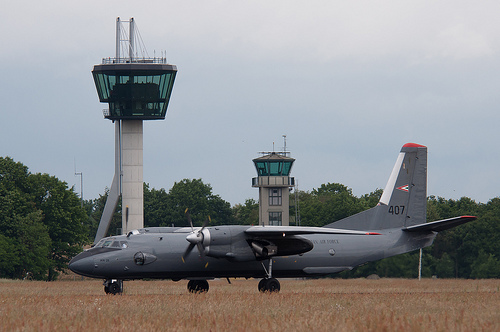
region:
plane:
[48, 186, 423, 270]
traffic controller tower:
[71, 32, 222, 204]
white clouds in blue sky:
[325, 26, 353, 56]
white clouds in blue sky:
[425, 58, 460, 90]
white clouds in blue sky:
[207, 62, 258, 104]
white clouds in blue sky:
[277, 45, 301, 69]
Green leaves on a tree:
[48, 222, 67, 239]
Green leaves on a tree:
[10, 237, 54, 282]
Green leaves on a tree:
[4, 198, 26, 234]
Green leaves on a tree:
[3, 148, 23, 205]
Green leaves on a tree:
[160, 168, 203, 196]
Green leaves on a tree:
[207, 194, 254, 222]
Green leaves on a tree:
[480, 203, 493, 279]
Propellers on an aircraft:
[178, 205, 211, 265]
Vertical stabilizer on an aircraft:
[321, 137, 428, 229]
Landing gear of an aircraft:
[101, 273, 283, 295]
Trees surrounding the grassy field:
[1, 151, 497, 283]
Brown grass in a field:
[3, 278, 488, 329]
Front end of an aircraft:
[62, 227, 188, 295]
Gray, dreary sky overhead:
[1, 3, 496, 207]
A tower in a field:
[87, 12, 177, 225]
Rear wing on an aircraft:
[400, 214, 476, 235]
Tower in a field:
[249, 143, 295, 223]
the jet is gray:
[68, 134, 473, 292]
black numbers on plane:
[386, 199, 409, 219]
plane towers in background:
[78, 16, 304, 227]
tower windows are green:
[92, 70, 170, 114]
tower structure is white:
[110, 113, 155, 236]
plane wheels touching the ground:
[99, 270, 287, 299]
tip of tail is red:
[393, 134, 423, 152]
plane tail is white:
[379, 146, 413, 206]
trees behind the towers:
[1, 146, 495, 287]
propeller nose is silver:
[185, 222, 213, 252]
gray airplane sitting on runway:
[61, 139, 478, 303]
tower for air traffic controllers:
[251, 130, 304, 222]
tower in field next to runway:
[81, 10, 179, 242]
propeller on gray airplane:
[178, 205, 215, 269]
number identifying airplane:
[384, 203, 406, 216]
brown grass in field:
[1, 276, 498, 330]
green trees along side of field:
[1, 153, 98, 277]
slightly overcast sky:
[6, 2, 499, 187]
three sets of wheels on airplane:
[101, 276, 288, 296]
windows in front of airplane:
[94, 235, 130, 250]